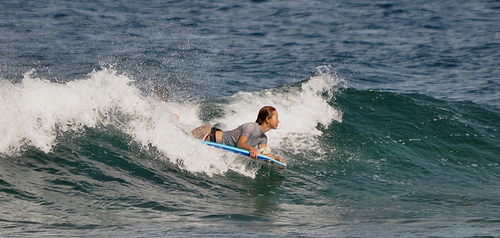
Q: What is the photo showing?
A: It is showing an ocean.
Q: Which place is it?
A: It is an ocean.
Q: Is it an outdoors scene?
A: Yes, it is outdoors.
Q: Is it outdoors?
A: Yes, it is outdoors.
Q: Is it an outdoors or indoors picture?
A: It is outdoors.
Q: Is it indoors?
A: No, it is outdoors.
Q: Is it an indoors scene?
A: No, it is outdoors.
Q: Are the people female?
A: No, they are both male and female.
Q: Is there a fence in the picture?
A: No, there are no fences.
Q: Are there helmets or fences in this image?
A: No, there are no fences or helmets.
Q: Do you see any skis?
A: No, there are no skis.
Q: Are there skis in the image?
A: No, there are no skis.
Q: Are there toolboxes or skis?
A: No, there are no skis or toolboxes.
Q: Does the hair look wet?
A: Yes, the hair is wet.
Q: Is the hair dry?
A: No, the hair is wet.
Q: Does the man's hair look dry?
A: No, the hair is wet.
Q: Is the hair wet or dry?
A: The hair is wet.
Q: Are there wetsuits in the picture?
A: Yes, there is a wetsuit.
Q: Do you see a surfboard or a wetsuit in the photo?
A: Yes, there is a wetsuit.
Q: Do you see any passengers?
A: No, there are no passengers.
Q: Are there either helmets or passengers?
A: No, there are no passengers or helmets.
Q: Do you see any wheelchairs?
A: No, there are no wheelchairs.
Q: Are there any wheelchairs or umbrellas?
A: No, there are no wheelchairs or umbrellas.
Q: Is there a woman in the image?
A: Yes, there is a woman.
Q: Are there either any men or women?
A: Yes, there is a woman.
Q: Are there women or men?
A: Yes, there is a woman.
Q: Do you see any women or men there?
A: Yes, there is a woman.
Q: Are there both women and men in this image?
A: Yes, there are both a woman and a man.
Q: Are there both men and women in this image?
A: Yes, there are both a woman and a man.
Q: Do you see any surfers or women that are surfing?
A: Yes, the woman is surfing.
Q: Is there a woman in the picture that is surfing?
A: Yes, there is a woman that is surfing.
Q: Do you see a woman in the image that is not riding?
A: Yes, there is a woman that is surfing .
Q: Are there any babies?
A: No, there are no babies.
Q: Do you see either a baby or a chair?
A: No, there are no babies or chairs.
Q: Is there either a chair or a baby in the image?
A: No, there are no babies or chairs.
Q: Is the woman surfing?
A: Yes, the woman is surfing.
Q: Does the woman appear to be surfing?
A: Yes, the woman is surfing.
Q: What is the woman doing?
A: The woman is surfing.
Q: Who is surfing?
A: The woman is surfing.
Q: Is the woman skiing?
A: No, the woman is surfing.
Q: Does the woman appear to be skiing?
A: No, the woman is surfing.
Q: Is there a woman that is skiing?
A: No, there is a woman but she is surfing.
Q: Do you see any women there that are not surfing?
A: No, there is a woman but she is surfing.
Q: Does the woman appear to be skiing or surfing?
A: The woman is surfing.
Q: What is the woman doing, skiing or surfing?
A: The woman is surfing.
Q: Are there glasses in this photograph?
A: No, there are no glasses.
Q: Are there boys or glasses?
A: No, there are no glasses or boys.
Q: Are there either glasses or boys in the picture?
A: No, there are no glasses or boys.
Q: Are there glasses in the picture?
A: No, there are no glasses.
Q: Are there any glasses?
A: No, there are no glasses.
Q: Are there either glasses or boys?
A: No, there are no glasses or boys.